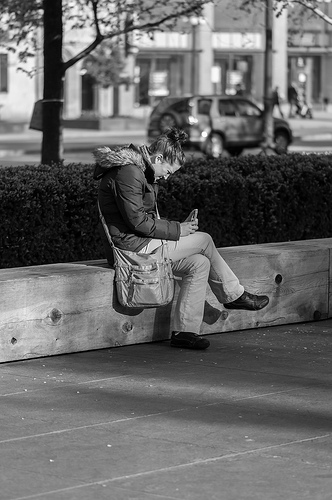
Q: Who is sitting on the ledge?
A: A woman.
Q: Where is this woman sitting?
A: On the ledge.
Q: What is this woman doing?
A: Sitting.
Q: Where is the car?
A: On the street.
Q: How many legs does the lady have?
A: Two.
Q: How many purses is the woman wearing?
A: One.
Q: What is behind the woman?
A: Bushes.